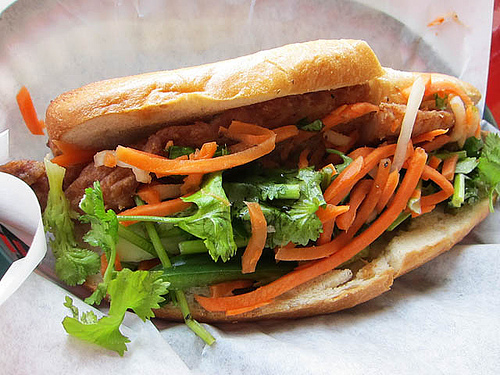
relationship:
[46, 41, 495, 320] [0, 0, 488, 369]
sandwich laying on parchment paper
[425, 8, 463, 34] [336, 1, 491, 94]
sauce on paper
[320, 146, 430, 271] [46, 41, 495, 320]
carrot on sandwich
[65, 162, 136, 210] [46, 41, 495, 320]
meat on sandwich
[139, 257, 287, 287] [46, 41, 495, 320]
bell pepper on sandwich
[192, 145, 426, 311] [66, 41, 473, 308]
carrot on sandwich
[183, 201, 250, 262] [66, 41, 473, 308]
lettuce on sandwich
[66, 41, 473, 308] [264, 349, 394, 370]
sandwich on parchment paper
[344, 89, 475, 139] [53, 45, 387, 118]
meat inside bread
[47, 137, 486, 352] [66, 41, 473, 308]
vegetables in sandwich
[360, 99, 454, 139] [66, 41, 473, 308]
meat in sandwich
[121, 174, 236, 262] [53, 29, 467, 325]
lettuce in sandwich